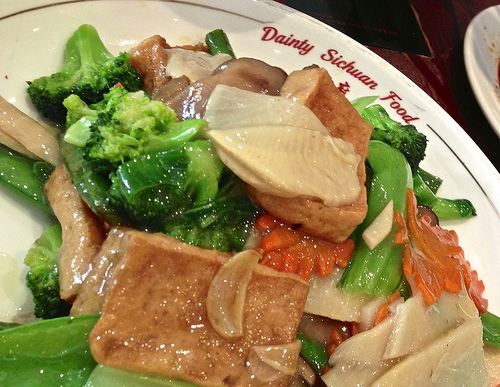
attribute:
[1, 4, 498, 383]
plate — filled with meat, filled with veggies, round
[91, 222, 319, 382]
meat — big chunk, big 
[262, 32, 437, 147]
letters — red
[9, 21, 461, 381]
meat — assorted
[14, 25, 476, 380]
veggies — assorted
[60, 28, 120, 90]
broccoli — green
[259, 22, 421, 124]
letters — Dainty Sichuan Food, dainty Sichuan 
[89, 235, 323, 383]
tofu — brown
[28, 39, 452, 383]
food — Dainty Sichuan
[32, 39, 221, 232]
broccoli — on a plate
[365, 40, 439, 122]
dish — white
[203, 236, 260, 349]
garlic — slice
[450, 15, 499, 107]
plate — another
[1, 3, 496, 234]
stripe — brown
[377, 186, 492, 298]
carrots — slices 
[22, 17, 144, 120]
broccoli — green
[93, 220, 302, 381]
chunk — big 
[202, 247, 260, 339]
garlic — pieces, little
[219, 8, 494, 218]
border — line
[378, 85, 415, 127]
food — Sichuan Food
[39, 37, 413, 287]
vegetables — green 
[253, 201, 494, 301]
carrots — on a plate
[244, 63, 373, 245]
tofu — brown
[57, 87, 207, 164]
broccoli — green